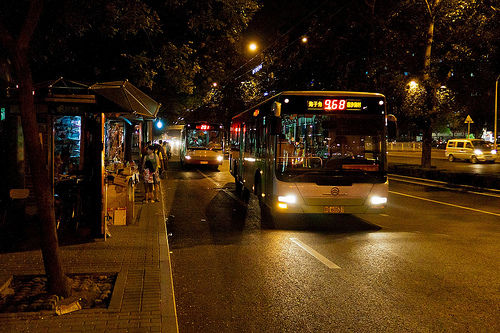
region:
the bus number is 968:
[321, 96, 346, 111]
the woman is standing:
[140, 146, 168, 201]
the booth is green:
[50, 117, 116, 241]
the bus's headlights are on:
[271, 185, 398, 215]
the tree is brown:
[10, 68, 81, 294]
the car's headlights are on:
[476, 150, 495, 159]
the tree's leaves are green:
[403, 84, 458, 139]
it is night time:
[8, 9, 498, 331]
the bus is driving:
[230, 73, 409, 252]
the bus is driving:
[176, 113, 228, 173]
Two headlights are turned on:
[273, 184, 394, 213]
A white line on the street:
[278, 229, 347, 270]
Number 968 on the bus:
[321, 96, 347, 113]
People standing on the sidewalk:
[133, 137, 170, 213]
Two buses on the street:
[170, 81, 498, 331]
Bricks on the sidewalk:
[0, 203, 161, 331]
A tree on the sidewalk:
[2, 1, 263, 328]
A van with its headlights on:
[441, 133, 499, 170]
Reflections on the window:
[275, 112, 383, 172]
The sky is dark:
[244, 1, 323, 33]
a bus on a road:
[225, 91, 385, 231]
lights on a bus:
[275, 195, 382, 210]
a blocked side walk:
[125, 225, 155, 311]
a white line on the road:
[285, 228, 340, 271]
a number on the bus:
[312, 97, 367, 113]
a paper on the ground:
[52, 299, 82, 317]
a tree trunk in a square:
[10, 266, 115, 314]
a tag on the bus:
[321, 205, 346, 218]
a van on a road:
[444, 136, 495, 166]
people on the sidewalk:
[143, 148, 160, 203]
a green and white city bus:
[225, 87, 401, 222]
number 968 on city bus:
[322, 99, 347, 116]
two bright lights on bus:
[277, 192, 390, 207]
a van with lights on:
[442, 138, 498, 166]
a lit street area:
[162, 144, 499, 331]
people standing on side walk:
[137, 139, 168, 204]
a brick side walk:
[0, 145, 180, 331]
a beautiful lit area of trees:
[0, 24, 499, 166]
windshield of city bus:
[269, 107, 389, 187]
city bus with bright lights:
[175, 115, 228, 171]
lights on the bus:
[273, 187, 311, 207]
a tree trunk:
[25, 165, 85, 295]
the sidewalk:
[122, 265, 167, 330]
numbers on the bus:
[321, 97, 346, 108]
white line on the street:
[292, 238, 343, 273]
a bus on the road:
[180, 121, 225, 161]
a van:
[445, 135, 495, 161]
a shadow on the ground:
[200, 183, 255, 235]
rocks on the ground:
[86, 270, 114, 288]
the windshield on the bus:
[280, 117, 380, 168]